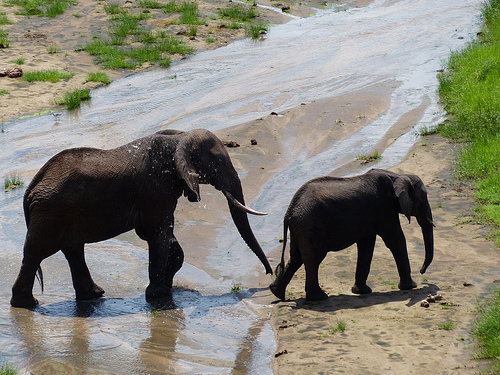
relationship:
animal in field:
[272, 167, 432, 311] [3, 1, 497, 372]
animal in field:
[13, 143, 270, 302] [3, 1, 497, 372]